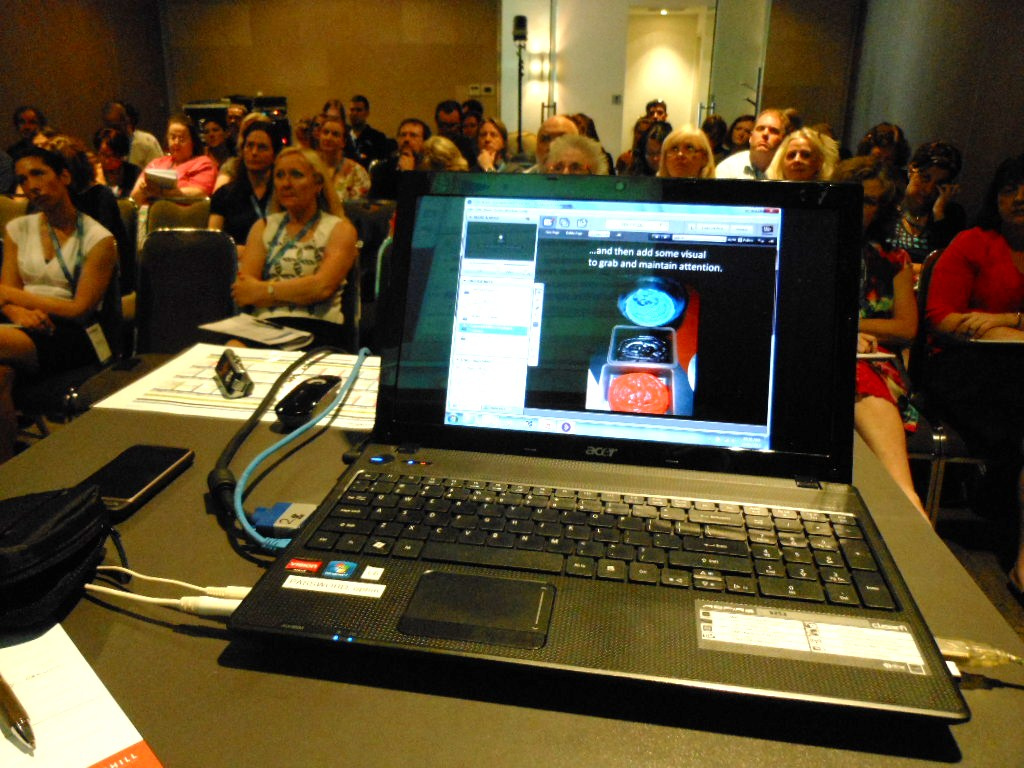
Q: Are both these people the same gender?
A: Yes, all the people are female.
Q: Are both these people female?
A: Yes, all the people are female.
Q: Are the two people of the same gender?
A: Yes, all the people are female.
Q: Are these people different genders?
A: No, all the people are female.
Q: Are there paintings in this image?
A: No, there are no paintings.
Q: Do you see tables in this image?
A: Yes, there is a table.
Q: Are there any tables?
A: Yes, there is a table.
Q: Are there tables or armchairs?
A: Yes, there is a table.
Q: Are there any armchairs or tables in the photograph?
A: Yes, there is a table.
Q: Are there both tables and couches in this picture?
A: No, there is a table but no couches.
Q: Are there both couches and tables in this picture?
A: No, there is a table but no couches.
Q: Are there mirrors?
A: No, there are no mirrors.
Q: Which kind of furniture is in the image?
A: The furniture is a table.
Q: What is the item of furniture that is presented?
A: The piece of furniture is a table.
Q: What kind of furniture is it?
A: The piece of furniture is a table.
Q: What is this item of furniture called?
A: This is a table.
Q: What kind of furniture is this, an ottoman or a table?
A: This is a table.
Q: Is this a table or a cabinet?
A: This is a table.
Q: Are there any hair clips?
A: No, there are no hair clips.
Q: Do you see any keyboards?
A: Yes, there is a keyboard.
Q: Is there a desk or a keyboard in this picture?
A: Yes, there is a keyboard.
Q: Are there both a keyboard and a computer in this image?
A: Yes, there are both a keyboard and a computer.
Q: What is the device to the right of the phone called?
A: The device is a keyboard.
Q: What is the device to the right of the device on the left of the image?
A: The device is a keyboard.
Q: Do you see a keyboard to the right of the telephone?
A: Yes, there is a keyboard to the right of the telephone.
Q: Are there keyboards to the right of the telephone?
A: Yes, there is a keyboard to the right of the telephone.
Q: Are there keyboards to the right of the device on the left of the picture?
A: Yes, there is a keyboard to the right of the telephone.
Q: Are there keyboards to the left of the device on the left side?
A: No, the keyboard is to the right of the phone.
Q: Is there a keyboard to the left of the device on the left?
A: No, the keyboard is to the right of the phone.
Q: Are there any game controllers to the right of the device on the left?
A: No, there is a keyboard to the right of the phone.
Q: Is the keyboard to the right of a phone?
A: Yes, the keyboard is to the right of a phone.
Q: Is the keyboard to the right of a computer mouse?
A: No, the keyboard is to the right of a phone.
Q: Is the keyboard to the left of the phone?
A: No, the keyboard is to the right of the phone.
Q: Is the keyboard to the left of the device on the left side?
A: No, the keyboard is to the right of the phone.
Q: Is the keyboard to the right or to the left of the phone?
A: The keyboard is to the right of the phone.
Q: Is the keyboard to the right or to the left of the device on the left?
A: The keyboard is to the right of the phone.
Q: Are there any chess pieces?
A: No, there are no chess pieces.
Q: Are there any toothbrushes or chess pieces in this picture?
A: No, there are no chess pieces or toothbrushes.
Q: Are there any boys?
A: No, there are no boys.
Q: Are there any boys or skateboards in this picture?
A: No, there are no boys or skateboards.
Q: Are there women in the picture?
A: Yes, there is a woman.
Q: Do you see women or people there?
A: Yes, there is a woman.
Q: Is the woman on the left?
A: Yes, the woman is on the left of the image.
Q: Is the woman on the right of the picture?
A: No, the woman is on the left of the image.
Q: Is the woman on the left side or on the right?
A: The woman is on the left of the image.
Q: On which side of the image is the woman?
A: The woman is on the left of the image.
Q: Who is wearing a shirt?
A: The woman is wearing a shirt.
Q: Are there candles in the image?
A: No, there are no candles.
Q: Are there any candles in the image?
A: No, there are no candles.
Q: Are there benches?
A: No, there are no benches.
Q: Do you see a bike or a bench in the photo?
A: No, there are no benches or bikes.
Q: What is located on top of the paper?
A: The pen is on top of the paper.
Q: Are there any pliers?
A: No, there are no pliers.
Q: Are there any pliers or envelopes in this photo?
A: No, there are no pliers or envelopes.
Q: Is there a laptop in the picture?
A: Yes, there is a laptop.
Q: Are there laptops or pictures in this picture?
A: Yes, there is a laptop.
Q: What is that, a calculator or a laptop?
A: That is a laptop.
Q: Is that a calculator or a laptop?
A: That is a laptop.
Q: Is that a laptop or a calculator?
A: That is a laptop.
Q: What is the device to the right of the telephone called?
A: The device is a laptop.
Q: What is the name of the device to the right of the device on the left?
A: The device is a laptop.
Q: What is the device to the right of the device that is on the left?
A: The device is a laptop.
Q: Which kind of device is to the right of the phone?
A: The device is a laptop.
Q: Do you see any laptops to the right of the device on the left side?
A: Yes, there is a laptop to the right of the telephone.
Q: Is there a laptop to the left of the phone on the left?
A: No, the laptop is to the right of the phone.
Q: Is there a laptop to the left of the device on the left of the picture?
A: No, the laptop is to the right of the phone.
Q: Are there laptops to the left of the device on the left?
A: No, the laptop is to the right of the phone.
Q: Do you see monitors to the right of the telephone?
A: No, there is a laptop to the right of the telephone.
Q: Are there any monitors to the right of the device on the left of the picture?
A: No, there is a laptop to the right of the telephone.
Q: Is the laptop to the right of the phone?
A: Yes, the laptop is to the right of the phone.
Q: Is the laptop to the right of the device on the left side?
A: Yes, the laptop is to the right of the phone.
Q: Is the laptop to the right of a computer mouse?
A: No, the laptop is to the right of the phone.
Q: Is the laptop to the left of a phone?
A: No, the laptop is to the right of a phone.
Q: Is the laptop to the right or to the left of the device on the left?
A: The laptop is to the right of the phone.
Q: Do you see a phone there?
A: Yes, there is a phone.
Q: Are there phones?
A: Yes, there is a phone.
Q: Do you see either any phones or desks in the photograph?
A: Yes, there is a phone.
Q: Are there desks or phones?
A: Yes, there is a phone.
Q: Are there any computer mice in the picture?
A: No, there are no computer mice.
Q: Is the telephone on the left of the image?
A: Yes, the telephone is on the left of the image.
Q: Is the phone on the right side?
A: No, the phone is on the left of the image.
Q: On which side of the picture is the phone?
A: The phone is on the left of the image.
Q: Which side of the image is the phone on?
A: The phone is on the left of the image.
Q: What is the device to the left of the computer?
A: The device is a phone.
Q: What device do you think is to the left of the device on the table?
A: The device is a phone.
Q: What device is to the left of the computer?
A: The device is a phone.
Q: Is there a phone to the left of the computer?
A: Yes, there is a phone to the left of the computer.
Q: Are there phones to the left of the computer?
A: Yes, there is a phone to the left of the computer.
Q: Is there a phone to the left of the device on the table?
A: Yes, there is a phone to the left of the computer.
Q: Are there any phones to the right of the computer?
A: No, the phone is to the left of the computer.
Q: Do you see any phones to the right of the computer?
A: No, the phone is to the left of the computer.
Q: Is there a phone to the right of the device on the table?
A: No, the phone is to the left of the computer.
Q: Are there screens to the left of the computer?
A: No, there is a phone to the left of the computer.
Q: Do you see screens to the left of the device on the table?
A: No, there is a phone to the left of the computer.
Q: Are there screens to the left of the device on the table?
A: No, there is a phone to the left of the computer.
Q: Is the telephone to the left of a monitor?
A: No, the telephone is to the left of a computer.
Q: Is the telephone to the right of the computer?
A: No, the telephone is to the left of the computer.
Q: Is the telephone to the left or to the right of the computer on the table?
A: The telephone is to the left of the computer.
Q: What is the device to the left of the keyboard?
A: The device is a phone.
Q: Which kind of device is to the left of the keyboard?
A: The device is a phone.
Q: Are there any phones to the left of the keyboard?
A: Yes, there is a phone to the left of the keyboard.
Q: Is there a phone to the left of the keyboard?
A: Yes, there is a phone to the left of the keyboard.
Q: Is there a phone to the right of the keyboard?
A: No, the phone is to the left of the keyboard.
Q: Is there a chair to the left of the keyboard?
A: No, there is a phone to the left of the keyboard.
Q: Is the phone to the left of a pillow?
A: No, the phone is to the left of the keyboard.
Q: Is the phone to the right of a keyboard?
A: No, the phone is to the left of a keyboard.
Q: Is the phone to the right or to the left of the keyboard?
A: The phone is to the left of the keyboard.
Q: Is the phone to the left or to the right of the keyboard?
A: The phone is to the left of the keyboard.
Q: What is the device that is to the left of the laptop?
A: The device is a phone.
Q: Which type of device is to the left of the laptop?
A: The device is a phone.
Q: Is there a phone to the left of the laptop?
A: Yes, there is a phone to the left of the laptop.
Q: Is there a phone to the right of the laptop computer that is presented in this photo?
A: No, the phone is to the left of the laptop computer.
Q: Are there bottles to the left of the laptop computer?
A: No, there is a phone to the left of the laptop computer.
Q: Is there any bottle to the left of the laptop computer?
A: No, there is a phone to the left of the laptop computer.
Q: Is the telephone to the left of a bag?
A: No, the telephone is to the left of the laptop.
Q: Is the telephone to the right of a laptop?
A: No, the telephone is to the left of a laptop.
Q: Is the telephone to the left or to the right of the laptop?
A: The telephone is to the left of the laptop.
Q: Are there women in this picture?
A: Yes, there is a woman.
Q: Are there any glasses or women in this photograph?
A: Yes, there is a woman.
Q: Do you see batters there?
A: No, there are no batters.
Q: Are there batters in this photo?
A: No, there are no batters.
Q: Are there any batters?
A: No, there are no batters.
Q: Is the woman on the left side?
A: Yes, the woman is on the left of the image.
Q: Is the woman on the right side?
A: No, the woman is on the left of the image.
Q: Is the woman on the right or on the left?
A: The woman is on the left of the image.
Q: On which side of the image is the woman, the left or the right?
A: The woman is on the left of the image.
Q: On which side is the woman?
A: The woman is on the left of the image.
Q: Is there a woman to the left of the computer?
A: Yes, there is a woman to the left of the computer.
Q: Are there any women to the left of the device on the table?
A: Yes, there is a woman to the left of the computer.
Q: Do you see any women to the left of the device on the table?
A: Yes, there is a woman to the left of the computer.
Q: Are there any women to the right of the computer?
A: No, the woman is to the left of the computer.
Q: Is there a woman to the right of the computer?
A: No, the woman is to the left of the computer.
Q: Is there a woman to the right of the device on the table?
A: No, the woman is to the left of the computer.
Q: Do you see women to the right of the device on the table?
A: No, the woman is to the left of the computer.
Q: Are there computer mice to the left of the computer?
A: No, there is a woman to the left of the computer.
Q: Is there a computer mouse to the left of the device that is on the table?
A: No, there is a woman to the left of the computer.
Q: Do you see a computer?
A: Yes, there is a computer.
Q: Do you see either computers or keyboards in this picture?
A: Yes, there is a computer.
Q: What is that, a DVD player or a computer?
A: That is a computer.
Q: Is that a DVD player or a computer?
A: That is a computer.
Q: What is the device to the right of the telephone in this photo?
A: The device is a computer.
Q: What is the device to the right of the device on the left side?
A: The device is a computer.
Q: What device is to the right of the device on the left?
A: The device is a computer.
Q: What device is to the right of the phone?
A: The device is a computer.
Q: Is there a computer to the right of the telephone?
A: Yes, there is a computer to the right of the telephone.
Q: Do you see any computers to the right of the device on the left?
A: Yes, there is a computer to the right of the telephone.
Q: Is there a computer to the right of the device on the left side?
A: Yes, there is a computer to the right of the telephone.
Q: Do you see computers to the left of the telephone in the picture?
A: No, the computer is to the right of the telephone.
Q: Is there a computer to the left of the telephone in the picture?
A: No, the computer is to the right of the telephone.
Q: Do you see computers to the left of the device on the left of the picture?
A: No, the computer is to the right of the telephone.